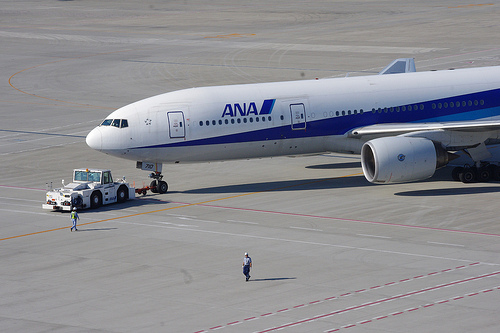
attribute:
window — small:
[332, 109, 340, 116]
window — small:
[408, 104, 412, 110]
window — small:
[166, 108, 188, 140]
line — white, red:
[197, 259, 482, 331]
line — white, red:
[257, 269, 497, 331]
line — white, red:
[321, 285, 498, 332]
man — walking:
[237, 248, 254, 281]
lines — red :
[243, 267, 498, 331]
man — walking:
[239, 252, 251, 282]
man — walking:
[223, 250, 280, 292]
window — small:
[203, 119, 212, 129]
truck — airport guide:
[39, 163, 144, 216]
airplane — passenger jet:
[79, 51, 498, 211]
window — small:
[207, 116, 218, 128]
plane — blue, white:
[81, 56, 498, 193]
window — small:
[238, 115, 244, 125]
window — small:
[256, 115, 262, 126]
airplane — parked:
[83, 54, 499, 196]